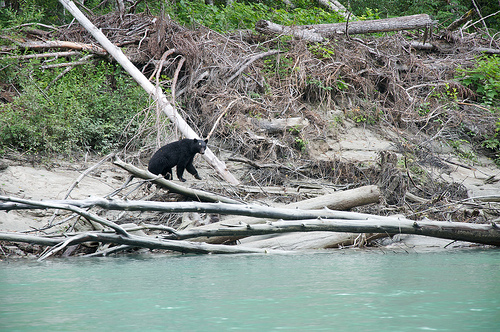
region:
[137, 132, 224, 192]
Black bear next to driftwood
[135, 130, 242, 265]
black bear on river bank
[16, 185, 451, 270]
Driftwood on river bank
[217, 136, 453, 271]
Fallen trees on river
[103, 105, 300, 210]
Black bear walking on river sand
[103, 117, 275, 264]
black bear walking on beach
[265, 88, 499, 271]
Fallen trees on beach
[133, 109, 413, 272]
black bear walking among fallen trees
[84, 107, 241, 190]
black bear next to green bush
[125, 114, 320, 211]
Black bear walking in storm debris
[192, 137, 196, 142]
The left ear of the bear.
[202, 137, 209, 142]
The right ear of the bear.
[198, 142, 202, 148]
The left eye of the bear.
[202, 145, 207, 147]
The right eye of the bear.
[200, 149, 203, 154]
The nose of the bear.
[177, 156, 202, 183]
The front legs of the bear.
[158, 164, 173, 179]
The back legs of the bear.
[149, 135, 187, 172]
The body of the bear.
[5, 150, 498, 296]
The tree logs in the water.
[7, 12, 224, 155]
The bushes behind the bear.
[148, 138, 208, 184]
A black bear on the shore.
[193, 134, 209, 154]
The head of a black bear.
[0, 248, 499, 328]
A body of green water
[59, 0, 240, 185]
A white tree trunk coming down beside a bear.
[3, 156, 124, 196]
Dirt patch behind the bear with no trees.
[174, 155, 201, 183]
Two front black arms of a black bear.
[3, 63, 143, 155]
Green bushes behind a black bear.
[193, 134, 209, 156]
Black head of a black bear.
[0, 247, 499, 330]
A body of water that appears green.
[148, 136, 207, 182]
A black bear over across the water.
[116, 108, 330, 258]
A black bear is on the beach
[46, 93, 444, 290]
Tree limbs are on the beach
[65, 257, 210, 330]
The water is blue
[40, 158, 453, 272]
Broken tree limbs are stacked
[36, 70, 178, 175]
bushes are underneath the trees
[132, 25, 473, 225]
Broken trees on the beach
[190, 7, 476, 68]
The tree leaves are green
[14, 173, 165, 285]
The beach has white sand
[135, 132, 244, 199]
The bear is sitting nex to the tree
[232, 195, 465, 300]
Tree trunks are by the water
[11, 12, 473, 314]
black bear in its habitat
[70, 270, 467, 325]
cloudy, calm water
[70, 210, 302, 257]
shoreline of logs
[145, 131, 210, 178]
bears turns toward the water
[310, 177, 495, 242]
accumulating driftwood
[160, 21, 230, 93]
tangle of vines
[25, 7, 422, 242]
bear steps through logs and branches washed ashore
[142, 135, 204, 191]
back feet on the ground, front paws on a log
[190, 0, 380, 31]
vegetation further away from shore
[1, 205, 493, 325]
a body of water and driftwood